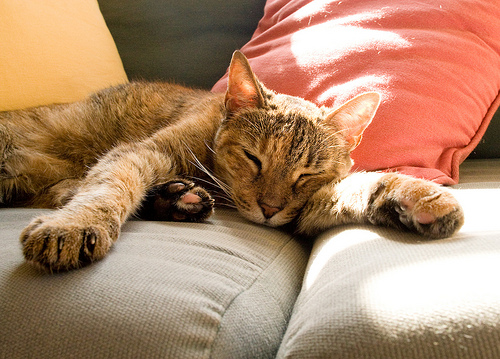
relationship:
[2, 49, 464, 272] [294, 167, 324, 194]
cat has right eye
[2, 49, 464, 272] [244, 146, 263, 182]
cat has left eye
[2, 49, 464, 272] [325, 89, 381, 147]
cat has right ear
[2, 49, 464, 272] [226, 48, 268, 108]
cat has left ear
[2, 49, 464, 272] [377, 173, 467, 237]
cat has paw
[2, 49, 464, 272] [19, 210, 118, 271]
cat has paw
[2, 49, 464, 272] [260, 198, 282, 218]
cat has a nose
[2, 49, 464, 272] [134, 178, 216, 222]
cat has back paw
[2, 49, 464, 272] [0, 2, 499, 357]
cat on couch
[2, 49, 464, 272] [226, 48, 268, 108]
cat has ear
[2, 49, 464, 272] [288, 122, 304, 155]
cat has stripe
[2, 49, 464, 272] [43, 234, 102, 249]
cat has nails